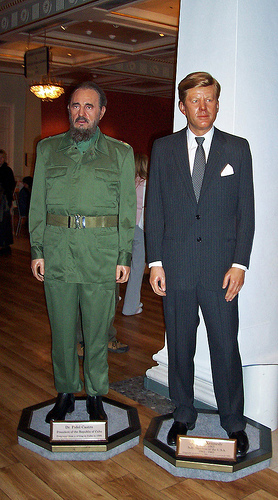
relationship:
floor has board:
[1, 232, 275, 499] [19, 455, 114, 498]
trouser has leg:
[161, 291, 249, 433] [198, 287, 250, 439]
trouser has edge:
[161, 291, 249, 433] [171, 406, 202, 429]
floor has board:
[1, 232, 275, 499] [163, 478, 225, 498]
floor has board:
[1, 232, 275, 499] [0, 327, 53, 372]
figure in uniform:
[25, 78, 134, 421] [24, 135, 138, 398]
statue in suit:
[143, 69, 250, 463] [143, 131, 255, 434]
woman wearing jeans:
[123, 149, 152, 314] [120, 225, 144, 311]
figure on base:
[25, 78, 134, 421] [15, 393, 144, 462]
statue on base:
[143, 69, 250, 463] [143, 410, 274, 482]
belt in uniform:
[45, 211, 119, 227] [24, 135, 138, 398]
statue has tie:
[143, 69, 250, 463] [188, 135, 208, 199]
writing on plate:
[54, 425, 102, 439] [47, 416, 107, 451]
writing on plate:
[182, 439, 235, 455] [172, 431, 242, 465]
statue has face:
[143, 69, 250, 463] [183, 84, 216, 127]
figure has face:
[25, 78, 134, 421] [68, 89, 101, 129]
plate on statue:
[47, 416, 107, 451] [25, 78, 134, 421]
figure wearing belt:
[25, 78, 134, 421] [45, 211, 119, 227]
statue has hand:
[143, 69, 250, 463] [219, 270, 251, 301]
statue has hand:
[143, 69, 250, 463] [146, 267, 169, 296]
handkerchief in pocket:
[219, 164, 235, 176] [218, 174, 237, 190]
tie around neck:
[188, 135, 208, 199] [183, 124, 215, 137]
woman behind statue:
[123, 149, 152, 314] [143, 69, 250, 463]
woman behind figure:
[123, 149, 152, 314] [25, 78, 134, 421]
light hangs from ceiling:
[27, 32, 65, 102] [3, 4, 178, 101]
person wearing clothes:
[0, 145, 22, 246] [0, 163, 16, 244]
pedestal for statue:
[143, 410, 274, 482] [143, 69, 250, 463]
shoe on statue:
[165, 421, 189, 448] [143, 69, 250, 463]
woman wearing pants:
[123, 149, 152, 314] [120, 225, 144, 311]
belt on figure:
[45, 211, 119, 227] [25, 78, 134, 421]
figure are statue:
[25, 78, 134, 421] [143, 69, 250, 463]